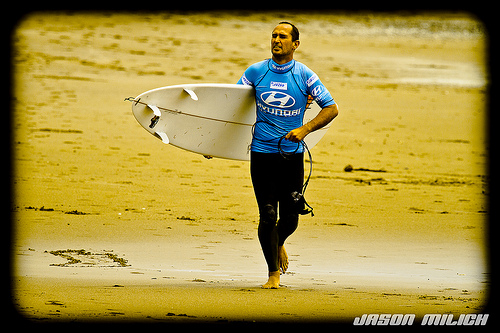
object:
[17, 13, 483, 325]
beach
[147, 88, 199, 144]
fin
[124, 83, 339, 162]
board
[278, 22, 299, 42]
hair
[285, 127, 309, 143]
hand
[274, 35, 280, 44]
nose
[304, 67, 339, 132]
arm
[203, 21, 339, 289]
guy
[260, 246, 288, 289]
shoes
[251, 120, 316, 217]
cable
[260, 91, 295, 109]
logo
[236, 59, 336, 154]
shirt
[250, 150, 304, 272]
wetsuit pants